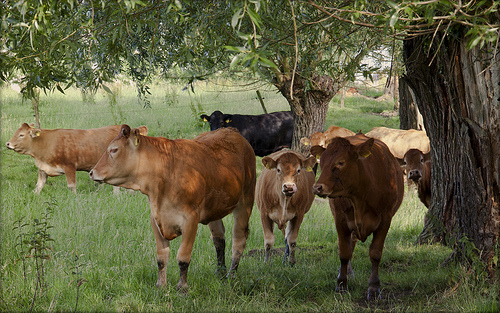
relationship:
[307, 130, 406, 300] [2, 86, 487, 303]
brown cow on grass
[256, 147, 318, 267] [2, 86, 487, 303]
brown cow on grass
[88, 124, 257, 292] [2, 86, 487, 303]
brown cow on grass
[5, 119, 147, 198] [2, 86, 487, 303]
brown cow on grass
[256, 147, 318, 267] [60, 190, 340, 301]
brown cow on grass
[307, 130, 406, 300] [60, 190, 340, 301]
brown cow on grass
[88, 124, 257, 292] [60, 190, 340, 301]
brown cow on grass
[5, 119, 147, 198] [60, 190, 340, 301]
brown cow on grass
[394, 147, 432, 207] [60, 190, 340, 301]
brown cow on grass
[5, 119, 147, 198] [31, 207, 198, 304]
brown cow on grass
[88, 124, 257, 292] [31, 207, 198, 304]
brown cow on grass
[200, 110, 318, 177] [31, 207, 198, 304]
black cow on grass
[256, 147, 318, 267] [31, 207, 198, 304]
brown cow on grass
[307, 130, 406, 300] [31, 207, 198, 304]
brown cow on grass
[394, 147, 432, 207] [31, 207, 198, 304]
brown cow on grass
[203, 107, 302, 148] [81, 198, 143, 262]
black cow on grass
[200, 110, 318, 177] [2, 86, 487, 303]
black cow on grass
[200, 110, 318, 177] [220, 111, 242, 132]
black cow tagged on ear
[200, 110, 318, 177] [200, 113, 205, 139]
black cow tagged on ear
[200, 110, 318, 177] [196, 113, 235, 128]
black cow has tags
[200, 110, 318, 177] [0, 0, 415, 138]
black cow behind tree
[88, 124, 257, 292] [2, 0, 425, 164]
brown cow behind tree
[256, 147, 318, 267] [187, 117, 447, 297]
brown cow facing camera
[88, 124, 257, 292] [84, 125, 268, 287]
brown cow showing face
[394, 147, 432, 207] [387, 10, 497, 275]
brown cow peeping tree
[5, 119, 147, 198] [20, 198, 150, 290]
brown cow standing grass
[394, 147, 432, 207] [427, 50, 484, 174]
brown cow peeping tree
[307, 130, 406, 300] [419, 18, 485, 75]
brown cow peeping tree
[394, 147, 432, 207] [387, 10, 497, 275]
brown cow sticking tree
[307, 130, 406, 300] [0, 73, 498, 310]
brown cow in field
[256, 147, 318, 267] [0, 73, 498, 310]
brown cow in field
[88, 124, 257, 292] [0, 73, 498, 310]
brown cow in field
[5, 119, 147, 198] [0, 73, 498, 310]
brown cow in field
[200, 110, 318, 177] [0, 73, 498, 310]
black cow in field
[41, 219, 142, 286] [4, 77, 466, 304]
grass in pasture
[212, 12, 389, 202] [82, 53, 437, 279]
tree around cows